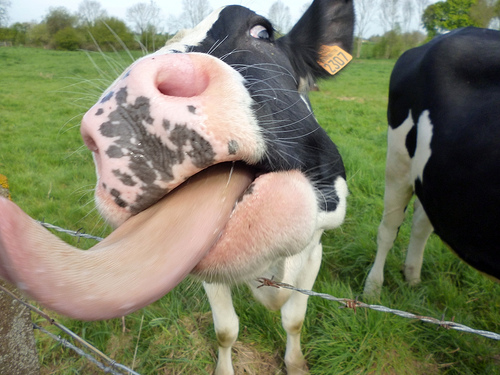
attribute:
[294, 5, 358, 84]
ear — tagged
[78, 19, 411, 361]
cow — white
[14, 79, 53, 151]
grass — patch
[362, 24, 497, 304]
cow — black , white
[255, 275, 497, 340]
barbed wire — grey, rusting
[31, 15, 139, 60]
trees — thick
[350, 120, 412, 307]
back leg — black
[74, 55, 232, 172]
nose — black, pink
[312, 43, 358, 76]
tag — orange